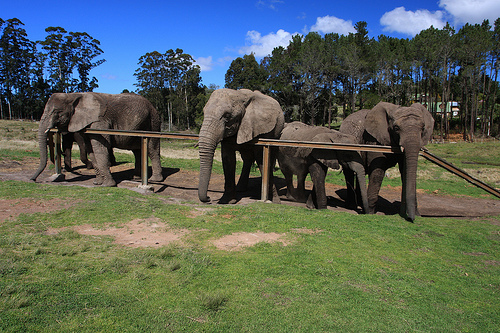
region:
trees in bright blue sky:
[2, 0, 104, 87]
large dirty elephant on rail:
[22, 76, 177, 206]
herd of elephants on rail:
[182, 60, 447, 234]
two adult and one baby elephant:
[184, 70, 447, 240]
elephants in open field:
[4, 7, 488, 324]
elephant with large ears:
[179, 73, 290, 220]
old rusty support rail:
[31, 115, 498, 243]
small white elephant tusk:
[42, 120, 62, 140]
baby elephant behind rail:
[272, 107, 374, 218]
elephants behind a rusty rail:
[6, 10, 496, 268]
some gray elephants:
[20, 67, 447, 235]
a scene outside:
[15, 22, 459, 332]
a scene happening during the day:
[3, 10, 492, 327]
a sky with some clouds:
[0, 0, 498, 129]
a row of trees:
[2, 12, 499, 163]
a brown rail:
[23, 113, 498, 236]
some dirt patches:
[46, 199, 341, 268]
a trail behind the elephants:
[1, 125, 497, 197]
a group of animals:
[26, 77, 441, 228]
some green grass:
[353, 237, 498, 328]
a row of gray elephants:
[29, 70, 444, 231]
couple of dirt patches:
[36, 204, 333, 279]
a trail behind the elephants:
[9, 125, 499, 186]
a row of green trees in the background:
[0, 18, 491, 158]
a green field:
[326, 218, 494, 329]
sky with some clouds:
[2, 0, 490, 110]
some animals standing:
[23, 78, 481, 245]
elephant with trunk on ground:
[190, 90, 285, 207]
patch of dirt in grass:
[89, 201, 202, 260]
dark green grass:
[42, 279, 132, 325]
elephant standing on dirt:
[34, 85, 164, 202]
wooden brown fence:
[35, 122, 447, 216]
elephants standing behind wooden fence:
[33, 76, 461, 217]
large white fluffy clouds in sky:
[231, 22, 300, 64]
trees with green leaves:
[297, 25, 477, 103]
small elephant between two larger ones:
[275, 111, 372, 213]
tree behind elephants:
[124, 54, 214, 122]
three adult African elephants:
[36, 87, 449, 214]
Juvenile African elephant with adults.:
[194, 95, 459, 205]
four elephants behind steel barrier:
[23, 95, 463, 221]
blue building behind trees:
[417, 98, 497, 121]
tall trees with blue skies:
[8, 20, 201, 95]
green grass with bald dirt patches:
[11, 190, 381, 310]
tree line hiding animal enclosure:
[240, 26, 495, 118]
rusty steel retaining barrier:
[47, 131, 430, 209]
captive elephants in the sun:
[37, 86, 432, 206]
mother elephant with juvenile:
[286, 92, 433, 226]